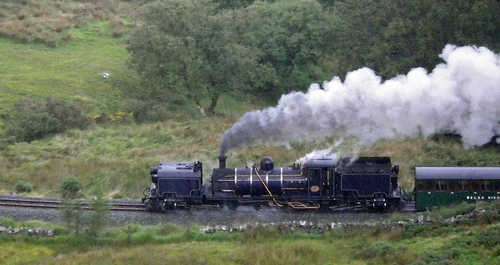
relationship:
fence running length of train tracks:
[2, 217, 479, 226] [0, 193, 141, 213]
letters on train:
[465, 190, 498, 204] [123, 140, 495, 216]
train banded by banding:
[165, 136, 475, 211] [214, 168, 307, 189]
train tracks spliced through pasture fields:
[0, 193, 141, 213] [12, 139, 140, 189]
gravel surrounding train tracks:
[2, 205, 285, 229] [0, 191, 144, 216]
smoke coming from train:
[202, 38, 497, 154] [147, 156, 500, 212]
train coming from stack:
[147, 156, 500, 212] [215, 155, 227, 170]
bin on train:
[346, 143, 411, 222] [113, 137, 460, 208]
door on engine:
[306, 166, 322, 202] [212, 147, 402, 210]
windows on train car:
[412, 181, 499, 193] [416, 161, 496, 216]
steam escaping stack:
[218, 44, 498, 172] [217, 153, 228, 168]